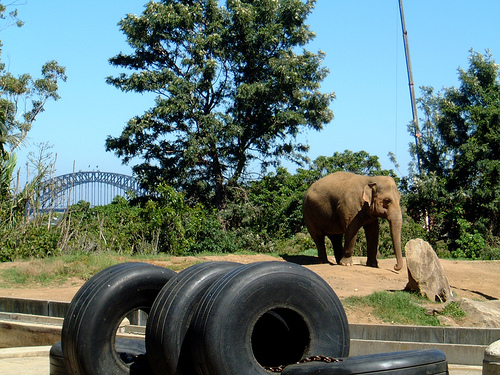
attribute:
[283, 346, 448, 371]
tire — rubber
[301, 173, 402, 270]
elephant — grey, brown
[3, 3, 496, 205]
sky — blue , Cloudless 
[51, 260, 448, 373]
tires — black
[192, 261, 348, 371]
tire — black, large, rubber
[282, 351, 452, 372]
tire — large, black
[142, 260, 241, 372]
tire — black, large, rubber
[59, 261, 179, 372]
tire — large, black, rubber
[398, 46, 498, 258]
tree — large, green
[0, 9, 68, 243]
tree — green, large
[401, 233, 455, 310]
stump — tree, brown, large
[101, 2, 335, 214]
tree — green, large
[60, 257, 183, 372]
tires — black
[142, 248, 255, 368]
tires — black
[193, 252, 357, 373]
tires — black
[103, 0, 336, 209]
leaves — green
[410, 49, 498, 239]
leaves — green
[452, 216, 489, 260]
leaves — green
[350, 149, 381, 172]
leaves — green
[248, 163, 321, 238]
leaves — green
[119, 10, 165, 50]
leaves — green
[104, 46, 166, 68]
leaves — green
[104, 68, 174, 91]
leaves — green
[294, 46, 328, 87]
leaves — green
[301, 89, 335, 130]
leaves — green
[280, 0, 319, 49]
leaves — green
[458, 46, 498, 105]
leaves — green